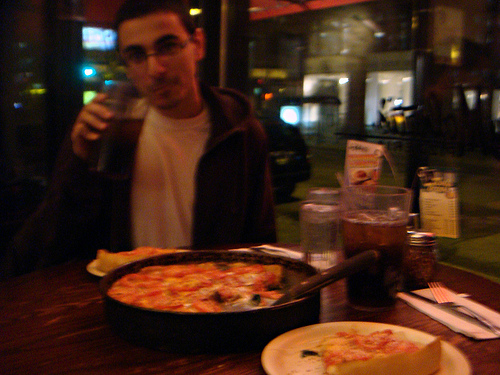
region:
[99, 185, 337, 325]
pizza is on the table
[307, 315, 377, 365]
pizza is on the plate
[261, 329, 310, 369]
the plate is white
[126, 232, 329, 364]
the pizza is deep dish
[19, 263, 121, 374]
the table is made of wood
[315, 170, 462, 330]
a drink is on the table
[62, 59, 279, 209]
a man is holding a drink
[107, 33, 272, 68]
a man is wearing glasses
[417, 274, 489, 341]
a fork is on the table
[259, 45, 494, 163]
a window is in the background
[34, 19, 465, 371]
a guy eating a deep dish meal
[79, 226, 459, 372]
this is a deep dish pizza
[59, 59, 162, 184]
he has a drink in his hand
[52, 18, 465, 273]
the picture is blurry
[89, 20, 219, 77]
he is wearing glasses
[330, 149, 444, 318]
a picture of pop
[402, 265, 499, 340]
silverwear on a napkin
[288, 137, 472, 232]
items in the area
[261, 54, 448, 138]
a blury background in the restaurant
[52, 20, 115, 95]
lights behind the man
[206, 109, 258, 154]
edge of a hood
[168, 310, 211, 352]
edge of a sufuria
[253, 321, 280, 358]
edge of a plate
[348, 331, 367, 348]
edge of a food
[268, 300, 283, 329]
edge of a sufuria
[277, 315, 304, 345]
part of a plate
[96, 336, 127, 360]
aprt of a table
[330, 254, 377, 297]
part of a handle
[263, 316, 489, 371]
A plate of food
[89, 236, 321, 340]
A plate of food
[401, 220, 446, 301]
This is a glass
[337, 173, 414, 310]
This is a glass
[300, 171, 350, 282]
This is a glass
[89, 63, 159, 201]
This is a glass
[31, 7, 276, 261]
This is a person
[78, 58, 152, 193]
a person holding glass in his hand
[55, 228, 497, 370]
things kept in the wooden table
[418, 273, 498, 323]
steel fork kept in the napkin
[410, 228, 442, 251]
lid of the bottle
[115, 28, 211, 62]
a person wearing eye glass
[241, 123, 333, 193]
a car parked near the building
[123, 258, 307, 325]
pizza with pizza cutter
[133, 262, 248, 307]
tomato and cheese toppings in the pizza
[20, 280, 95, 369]
wooden dining table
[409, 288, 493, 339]
napkin kept in the dining table